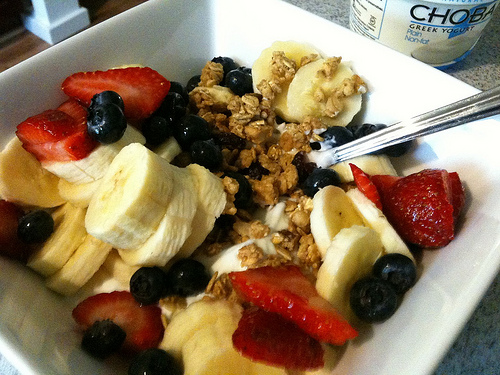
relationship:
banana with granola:
[312, 221, 383, 323] [183, 49, 368, 271]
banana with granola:
[306, 182, 370, 265] [183, 49, 368, 271]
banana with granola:
[0, 131, 72, 211] [183, 49, 368, 271]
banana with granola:
[78, 138, 181, 257] [183, 49, 368, 271]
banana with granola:
[24, 201, 93, 280] [183, 49, 368, 271]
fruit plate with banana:
[0, 38, 475, 375] [0, 131, 72, 211]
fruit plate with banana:
[0, 38, 475, 375] [24, 201, 93, 280]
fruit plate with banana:
[0, 38, 475, 375] [78, 138, 181, 257]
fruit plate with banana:
[0, 38, 475, 375] [306, 182, 370, 265]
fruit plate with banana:
[0, 38, 475, 375] [312, 221, 383, 323]